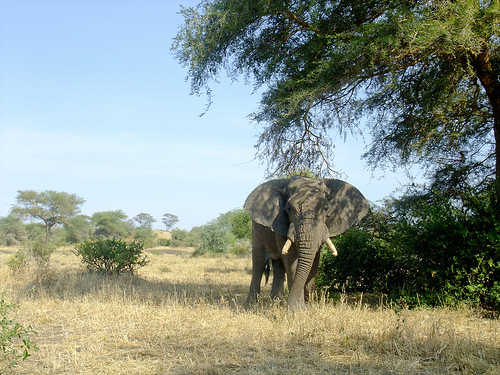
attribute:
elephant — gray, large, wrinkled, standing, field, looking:
[222, 173, 372, 308]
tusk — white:
[272, 227, 297, 266]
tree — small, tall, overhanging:
[70, 232, 155, 297]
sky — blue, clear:
[26, 26, 151, 160]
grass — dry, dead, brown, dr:
[118, 293, 220, 356]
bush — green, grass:
[347, 232, 474, 287]